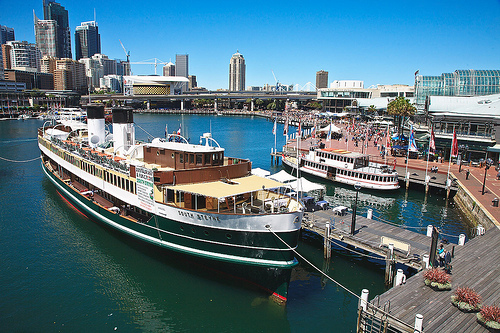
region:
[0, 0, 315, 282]
big boat--cruise ship, in fact--in front of big city, behind it too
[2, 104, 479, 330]
cove with stunningly coloured blue green water, probably assisted maybe a little slightly, maybe, in photoshop, maybe, ha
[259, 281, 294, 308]
red stripe near the very bottom of the boat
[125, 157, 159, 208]
a poster announcing something in black & green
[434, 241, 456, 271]
two tiny people, one in a turquoise shirt, the other bending down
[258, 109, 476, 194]
a long line of drooping flags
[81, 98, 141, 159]
two smokestacks, white & black top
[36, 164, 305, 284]
a green stripe near the boat's bottom, blink & you'll miss it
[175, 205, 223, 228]
ship's name, blurry in photo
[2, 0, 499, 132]
a variety of skyscrapers & one rounded greenhouse-like [but NOT greenhouse] glass building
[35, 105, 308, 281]
a large boat tied to the dock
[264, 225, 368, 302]
a cable attaching a boat to the dock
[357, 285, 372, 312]
a white post on a dock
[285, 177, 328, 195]
a white tarp providing shade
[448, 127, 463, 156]
a red flag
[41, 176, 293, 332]
the reflection of a large boat int he water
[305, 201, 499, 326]
a wooden dock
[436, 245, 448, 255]
a person in a blue shirt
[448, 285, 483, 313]
a flowery decoration on a dock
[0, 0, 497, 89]
a beautiful blue sky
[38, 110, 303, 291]
a very large cruise boat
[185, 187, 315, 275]
the front end of a boat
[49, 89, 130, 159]
two large pillars on a boat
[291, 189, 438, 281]
the end of a beach pier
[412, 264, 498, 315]
a bunch of potted flowers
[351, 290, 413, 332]
the railing on a pier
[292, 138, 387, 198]
a small passenger boat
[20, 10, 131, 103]
a bunch of city building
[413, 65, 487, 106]
a building made out of glass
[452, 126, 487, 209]
a bunch of black street lights